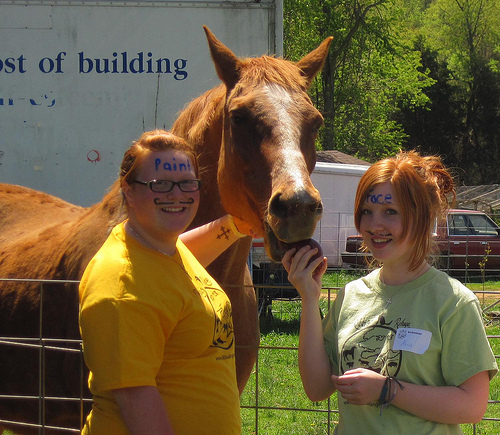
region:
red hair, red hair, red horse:
[0, 14, 468, 433]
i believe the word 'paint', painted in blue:
[145, 149, 196, 176]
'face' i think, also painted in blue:
[355, 185, 400, 206]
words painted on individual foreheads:
[135, 150, 406, 215]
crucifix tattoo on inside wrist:
[215, 224, 234, 244]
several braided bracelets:
[370, 371, 407, 416]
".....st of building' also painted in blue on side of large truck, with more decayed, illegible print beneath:
[2, 39, 198, 92]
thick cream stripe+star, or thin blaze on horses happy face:
[245, 74, 313, 198]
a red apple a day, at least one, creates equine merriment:
[269, 233, 329, 273]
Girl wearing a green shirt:
[280, 131, 497, 428]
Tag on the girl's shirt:
[379, 313, 443, 360]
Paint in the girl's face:
[358, 181, 400, 209]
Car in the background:
[347, 183, 499, 280]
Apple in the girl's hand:
[283, 231, 330, 280]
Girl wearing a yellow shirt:
[52, 108, 254, 434]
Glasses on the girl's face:
[137, 169, 202, 200]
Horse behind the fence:
[0, 36, 346, 433]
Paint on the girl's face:
[147, 144, 197, 179]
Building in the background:
[254, 126, 395, 276]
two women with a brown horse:
[2, 24, 494, 434]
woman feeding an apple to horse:
[268, 143, 498, 433]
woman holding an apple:
[276, 143, 499, 434]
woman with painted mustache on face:
[78, 130, 250, 434]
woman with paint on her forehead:
[78, 126, 250, 433]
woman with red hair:
[283, 146, 497, 433]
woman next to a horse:
[74, 128, 250, 433]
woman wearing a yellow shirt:
[76, 128, 241, 433]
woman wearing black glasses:
[76, 132, 244, 434]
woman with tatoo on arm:
[76, 130, 251, 434]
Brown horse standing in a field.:
[0, 23, 333, 434]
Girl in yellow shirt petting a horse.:
[76, 128, 264, 434]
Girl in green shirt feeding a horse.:
[280, 149, 498, 433]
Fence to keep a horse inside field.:
[1, 275, 498, 434]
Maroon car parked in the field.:
[339, 205, 497, 283]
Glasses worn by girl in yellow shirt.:
[121, 177, 203, 194]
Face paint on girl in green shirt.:
[359, 191, 396, 239]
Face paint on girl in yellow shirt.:
[149, 154, 195, 211]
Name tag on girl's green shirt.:
[388, 326, 434, 356]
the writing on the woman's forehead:
[149, 153, 197, 178]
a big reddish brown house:
[6, 28, 336, 403]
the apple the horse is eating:
[278, 243, 323, 270]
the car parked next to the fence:
[358, 208, 498, 265]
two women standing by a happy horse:
[83, 127, 488, 433]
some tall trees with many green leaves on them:
[283, 5, 498, 164]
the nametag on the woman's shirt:
[390, 327, 432, 357]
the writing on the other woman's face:
[362, 188, 392, 204]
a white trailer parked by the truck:
[298, 157, 375, 285]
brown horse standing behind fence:
[2, 24, 339, 289]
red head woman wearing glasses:
[120, 131, 203, 241]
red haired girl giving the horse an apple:
[280, 146, 459, 406]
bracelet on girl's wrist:
[373, 368, 401, 413]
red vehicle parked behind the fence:
[425, 209, 497, 282]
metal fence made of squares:
[0, 280, 297, 433]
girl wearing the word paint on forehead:
[115, 128, 204, 241]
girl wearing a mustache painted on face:
[351, 151, 451, 266]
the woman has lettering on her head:
[151, 153, 195, 173]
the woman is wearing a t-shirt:
[68, 216, 245, 426]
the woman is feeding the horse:
[283, 234, 320, 276]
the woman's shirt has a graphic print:
[192, 274, 236, 355]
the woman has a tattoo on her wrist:
[217, 223, 232, 239]